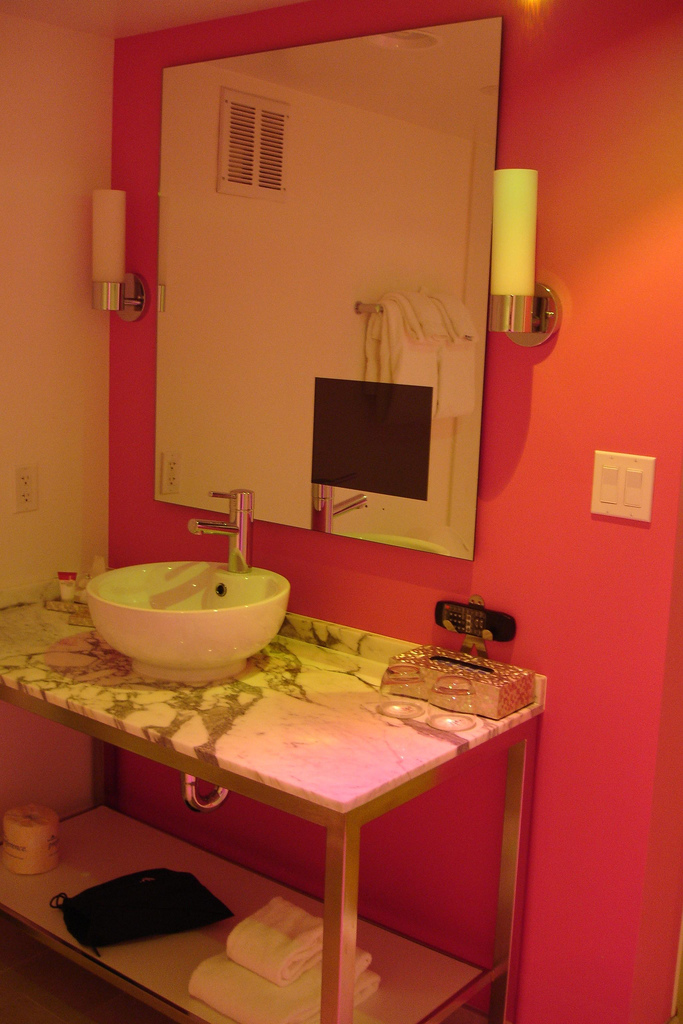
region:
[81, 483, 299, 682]
white sink with a silver faucet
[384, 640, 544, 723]
a box of tissue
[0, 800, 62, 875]
a roll of toilet paper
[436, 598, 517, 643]
a black remote control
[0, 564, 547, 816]
a marble counter top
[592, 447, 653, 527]
white light switch box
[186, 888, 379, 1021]
stack of white towels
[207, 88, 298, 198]
white air vent on the wall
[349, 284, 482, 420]
towels on a towel rack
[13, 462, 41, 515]
power outlet on the wall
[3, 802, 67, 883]
a roll of white toilet paper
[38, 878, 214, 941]
a bag that is black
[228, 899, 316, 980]
a small white towel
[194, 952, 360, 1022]
a large white towel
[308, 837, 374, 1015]
the leg of a counter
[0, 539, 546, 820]
a counter in a bathroom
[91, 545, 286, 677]
a sink that is white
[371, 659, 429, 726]
a small clear glass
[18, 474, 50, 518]
a small white outlet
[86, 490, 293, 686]
A white sink and faucet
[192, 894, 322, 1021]
A set of white towels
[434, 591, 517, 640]
A black remote control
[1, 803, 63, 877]
A roll of toilet tissue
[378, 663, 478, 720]
Two clear glasses on the sink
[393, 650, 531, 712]
A kleenex box with a flower design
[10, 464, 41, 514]
A electrical outlet on the wall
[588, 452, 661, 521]
A light switch on the wall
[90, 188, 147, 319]
A wall lamp with a white globe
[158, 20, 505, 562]
A large mirror on the wall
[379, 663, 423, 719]
Glass on counter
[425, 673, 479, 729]
Glass on counter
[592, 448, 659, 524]
Switch on the wall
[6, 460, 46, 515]
Plug on the wall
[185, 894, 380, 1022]
Towels under the counter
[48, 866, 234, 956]
Black bag under the counter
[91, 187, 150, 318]
Lamp next to the mirror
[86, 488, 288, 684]
White sink with silver faucet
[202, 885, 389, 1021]
Folded white towels on the bottom of stand.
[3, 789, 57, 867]
Wrapped up roll of toilet tissue.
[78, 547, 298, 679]
Small white bowl as the sink.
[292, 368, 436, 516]
Small mirror on the side of the wall.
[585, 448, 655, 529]
White light switch on the side of the wall.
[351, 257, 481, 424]
Two hand towels on the rail.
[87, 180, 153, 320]
Small light fixture on the wall.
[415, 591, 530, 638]
Remote control in the bathroom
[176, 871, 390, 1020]
White towels underneath sink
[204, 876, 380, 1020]
White towels on a shelf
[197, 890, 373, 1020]
White towels under counter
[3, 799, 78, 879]
Toilet paper underneath the sink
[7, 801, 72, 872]
Toilet paper in the wrapper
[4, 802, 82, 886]
Toilet paper on a shelf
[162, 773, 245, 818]
Silver pipe underneath sink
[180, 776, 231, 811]
Silver pipe underneath the counter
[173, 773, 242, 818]
Pipe underneath the sink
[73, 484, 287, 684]
A white ceramic above-counter sink with a chrome single-handle spout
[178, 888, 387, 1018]
A stack of white towels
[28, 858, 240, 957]
A black bag with a string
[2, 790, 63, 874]
A paper-wrapped toilet paper roll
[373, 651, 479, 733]
A pair of empty glass jars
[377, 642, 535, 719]
An empty tissue holder